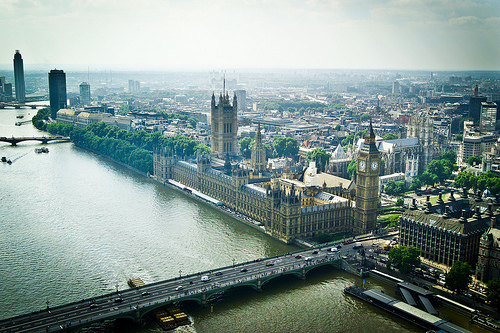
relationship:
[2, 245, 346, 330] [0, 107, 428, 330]
bridge over water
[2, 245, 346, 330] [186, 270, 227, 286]
bridge has vehicles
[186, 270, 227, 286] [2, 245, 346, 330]
vehicles on bridge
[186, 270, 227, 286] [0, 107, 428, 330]
vehicles over water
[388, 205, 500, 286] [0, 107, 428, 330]
buildings along water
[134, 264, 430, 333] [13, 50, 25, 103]
river next to building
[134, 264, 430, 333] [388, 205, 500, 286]
river next to buildings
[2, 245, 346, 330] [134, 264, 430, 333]
bridge covering river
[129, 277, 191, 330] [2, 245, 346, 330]
boat below bridge